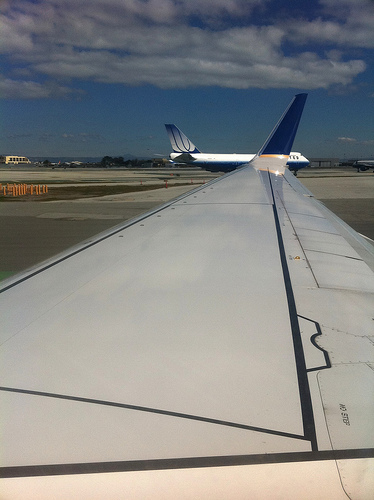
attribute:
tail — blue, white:
[162, 118, 194, 154]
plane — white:
[155, 115, 313, 185]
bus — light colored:
[1, 154, 34, 166]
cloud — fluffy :
[32, 44, 364, 89]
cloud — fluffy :
[10, 20, 295, 65]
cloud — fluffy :
[2, 2, 268, 27]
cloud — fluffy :
[311, 2, 369, 36]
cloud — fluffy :
[1, 71, 77, 100]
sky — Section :
[1, 3, 372, 92]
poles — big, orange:
[3, 177, 51, 197]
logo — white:
[165, 124, 201, 155]